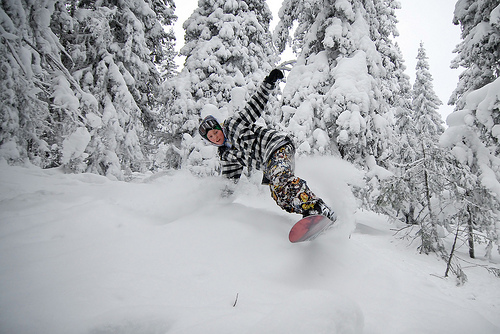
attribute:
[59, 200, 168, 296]
snow — thick, white, deep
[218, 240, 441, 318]
ground — white, close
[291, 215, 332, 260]
board — red, pink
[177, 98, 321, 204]
woman — flying, snowboarding, close, white, skiing, jumping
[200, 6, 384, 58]
trees — green, behind, covered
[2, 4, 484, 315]
snow — white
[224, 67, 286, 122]
arm — extended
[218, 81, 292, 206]
jacket — black